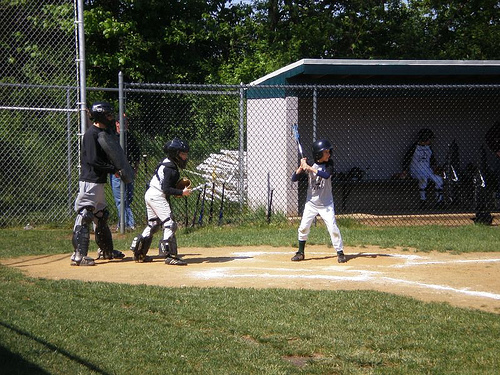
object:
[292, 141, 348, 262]
boy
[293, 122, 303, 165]
bat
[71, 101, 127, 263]
umpire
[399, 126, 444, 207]
player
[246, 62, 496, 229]
dugout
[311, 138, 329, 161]
helmet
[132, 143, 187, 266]
boy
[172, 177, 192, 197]
mitt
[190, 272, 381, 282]
lines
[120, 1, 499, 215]
fence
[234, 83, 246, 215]
posts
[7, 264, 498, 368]
field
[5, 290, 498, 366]
grass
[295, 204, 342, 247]
pants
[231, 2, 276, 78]
trees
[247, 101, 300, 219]
wall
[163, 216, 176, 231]
knee pads